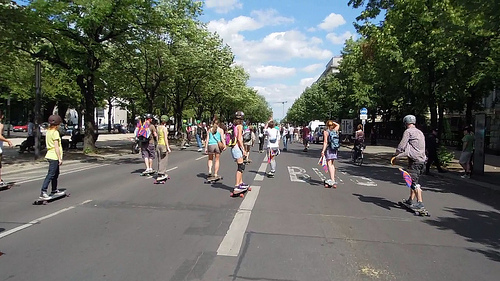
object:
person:
[231, 110, 254, 193]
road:
[103, 99, 437, 228]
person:
[204, 116, 229, 179]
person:
[38, 117, 68, 200]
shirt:
[41, 129, 66, 161]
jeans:
[40, 158, 63, 195]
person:
[389, 114, 435, 211]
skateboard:
[398, 199, 431, 217]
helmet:
[235, 108, 244, 118]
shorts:
[230, 146, 245, 159]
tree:
[359, 0, 498, 183]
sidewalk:
[365, 126, 499, 186]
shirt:
[206, 130, 223, 145]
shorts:
[206, 145, 224, 155]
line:
[223, 158, 269, 238]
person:
[317, 120, 348, 186]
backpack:
[327, 128, 342, 150]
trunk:
[424, 96, 442, 139]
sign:
[340, 119, 354, 135]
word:
[287, 165, 314, 183]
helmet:
[400, 114, 419, 126]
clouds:
[213, 18, 296, 71]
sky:
[162, 3, 360, 127]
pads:
[241, 163, 246, 171]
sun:
[341, 4, 392, 50]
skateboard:
[323, 177, 337, 189]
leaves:
[451, 22, 475, 42]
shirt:
[265, 129, 283, 149]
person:
[350, 124, 367, 160]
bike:
[348, 145, 366, 167]